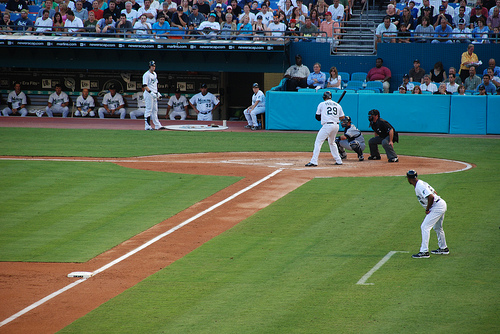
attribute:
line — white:
[358, 279, 376, 285]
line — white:
[358, 249, 401, 285]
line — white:
[390, 248, 410, 254]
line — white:
[360, 280, 371, 288]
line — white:
[354, 249, 399, 286]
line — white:
[0, 168, 279, 328]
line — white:
[2, 154, 221, 166]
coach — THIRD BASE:
[402, 168, 455, 259]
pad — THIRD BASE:
[64, 267, 98, 282]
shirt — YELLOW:
[454, 50, 484, 73]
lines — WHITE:
[352, 244, 413, 290]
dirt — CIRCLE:
[123, 141, 479, 184]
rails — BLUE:
[3, 21, 336, 66]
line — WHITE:
[4, 160, 291, 330]